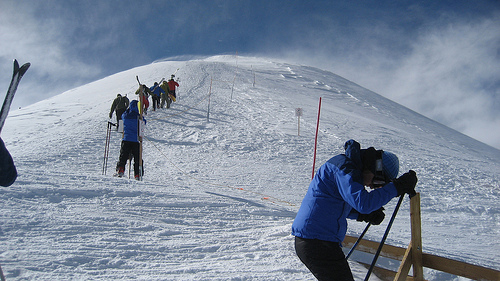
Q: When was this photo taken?
A: Daytime.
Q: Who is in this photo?
A: Skiers.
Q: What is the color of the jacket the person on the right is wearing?
A: Blue.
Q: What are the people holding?
A: Their skis.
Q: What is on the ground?
A: Snow.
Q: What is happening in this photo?
A: Skiers are climbing a mountain.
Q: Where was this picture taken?
A: On a ski slope.